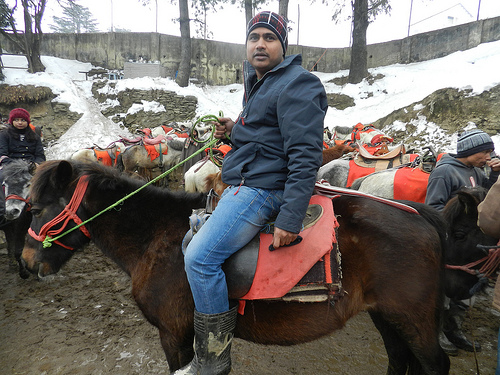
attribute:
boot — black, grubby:
[169, 301, 244, 373]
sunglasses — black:
[269, 234, 304, 253]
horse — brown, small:
[28, 169, 183, 373]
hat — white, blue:
[451, 124, 496, 159]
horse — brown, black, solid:
[16, 150, 462, 374]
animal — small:
[157, 116, 237, 189]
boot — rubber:
[170, 308, 235, 374]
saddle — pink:
[162, 115, 387, 306]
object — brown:
[267, 236, 303, 253]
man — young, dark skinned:
[171, 11, 327, 373]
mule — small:
[15, 155, 454, 372]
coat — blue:
[222, 55, 325, 236]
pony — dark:
[21, 161, 452, 373]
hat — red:
[9, 107, 29, 124]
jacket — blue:
[214, 48, 329, 233]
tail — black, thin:
[410, 201, 447, 341]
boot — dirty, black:
[165, 309, 242, 373]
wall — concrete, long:
[73, 30, 146, 59]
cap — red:
[2, 102, 32, 126]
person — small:
[0, 106, 43, 167]